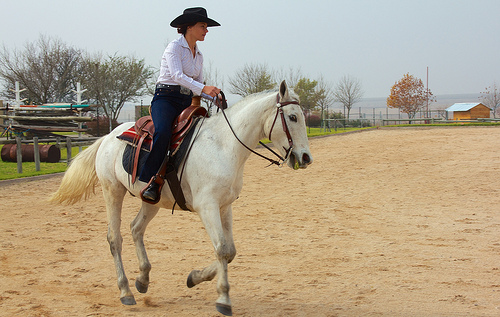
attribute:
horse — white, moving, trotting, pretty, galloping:
[50, 80, 312, 316]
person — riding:
[144, 8, 227, 200]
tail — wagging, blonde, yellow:
[50, 134, 103, 205]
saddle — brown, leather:
[132, 96, 211, 182]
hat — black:
[170, 8, 221, 28]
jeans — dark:
[139, 89, 192, 181]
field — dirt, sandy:
[0, 126, 499, 316]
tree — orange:
[387, 73, 436, 124]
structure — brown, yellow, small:
[446, 103, 492, 124]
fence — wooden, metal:
[1, 118, 499, 172]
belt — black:
[156, 85, 181, 90]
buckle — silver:
[179, 86, 191, 95]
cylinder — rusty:
[1, 144, 60, 162]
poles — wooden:
[1, 108, 96, 133]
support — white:
[11, 82, 26, 115]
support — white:
[71, 82, 88, 150]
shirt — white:
[156, 36, 203, 96]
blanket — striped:
[116, 121, 185, 157]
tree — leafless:
[333, 76, 364, 123]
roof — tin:
[445, 102, 492, 111]